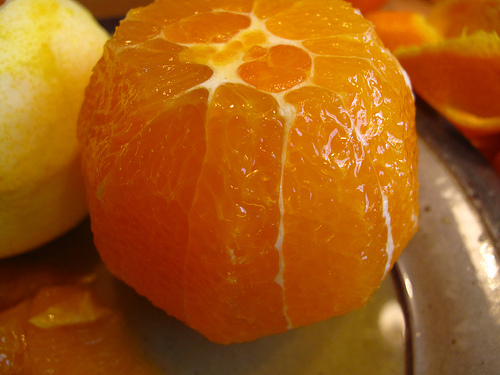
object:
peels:
[386, 2, 498, 154]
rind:
[368, 12, 498, 140]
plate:
[0, 99, 500, 370]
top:
[126, 26, 348, 104]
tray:
[414, 193, 498, 304]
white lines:
[92, 0, 418, 332]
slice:
[166, 72, 301, 347]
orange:
[80, 2, 440, 337]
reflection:
[434, 176, 496, 311]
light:
[449, 205, 497, 292]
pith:
[398, 31, 497, 52]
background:
[78, 2, 497, 157]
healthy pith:
[199, 15, 290, 78]